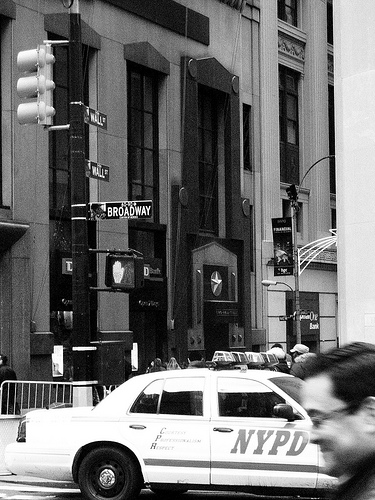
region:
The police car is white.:
[9, 361, 372, 499]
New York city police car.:
[3, 360, 373, 498]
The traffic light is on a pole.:
[8, 0, 98, 386]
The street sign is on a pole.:
[68, 189, 155, 380]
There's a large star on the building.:
[195, 253, 238, 302]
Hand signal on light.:
[79, 240, 150, 293]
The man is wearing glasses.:
[291, 323, 374, 498]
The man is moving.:
[281, 330, 373, 498]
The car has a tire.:
[70, 436, 149, 499]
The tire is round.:
[65, 441, 146, 498]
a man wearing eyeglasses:
[295, 347, 374, 491]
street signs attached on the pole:
[59, 69, 167, 375]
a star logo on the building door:
[196, 248, 254, 316]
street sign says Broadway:
[81, 187, 170, 230]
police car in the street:
[21, 319, 341, 495]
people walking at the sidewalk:
[139, 326, 261, 372]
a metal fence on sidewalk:
[3, 368, 110, 428]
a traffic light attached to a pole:
[11, 23, 60, 136]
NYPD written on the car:
[147, 411, 333, 480]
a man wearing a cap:
[281, 339, 314, 363]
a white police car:
[14, 362, 364, 495]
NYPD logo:
[227, 427, 306, 458]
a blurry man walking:
[291, 339, 372, 498]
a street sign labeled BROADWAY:
[88, 196, 161, 225]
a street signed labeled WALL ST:
[81, 158, 112, 182]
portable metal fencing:
[1, 376, 71, 417]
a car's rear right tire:
[76, 444, 140, 498]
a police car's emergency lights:
[211, 349, 275, 367]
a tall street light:
[258, 245, 308, 348]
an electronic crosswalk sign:
[100, 250, 135, 292]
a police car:
[16, 285, 333, 497]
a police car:
[56, 353, 320, 471]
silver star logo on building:
[199, 263, 235, 299]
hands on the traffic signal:
[96, 257, 146, 296]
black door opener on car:
[200, 423, 240, 436]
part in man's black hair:
[279, 337, 367, 366]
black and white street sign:
[46, 86, 139, 127]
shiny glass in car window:
[134, 372, 287, 413]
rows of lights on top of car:
[202, 342, 283, 369]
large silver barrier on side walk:
[6, 366, 106, 405]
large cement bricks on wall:
[319, 287, 338, 348]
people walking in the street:
[190, 325, 340, 391]